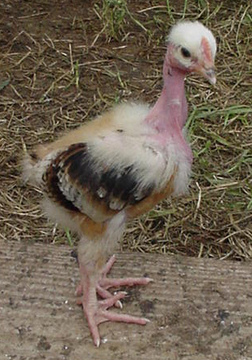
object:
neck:
[157, 80, 191, 117]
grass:
[0, 0, 252, 263]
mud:
[23, 7, 69, 32]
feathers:
[45, 136, 173, 220]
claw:
[76, 253, 155, 309]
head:
[169, 18, 219, 85]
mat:
[167, 273, 209, 324]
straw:
[225, 37, 246, 175]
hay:
[199, 99, 251, 179]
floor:
[151, 257, 238, 352]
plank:
[0, 232, 251, 360]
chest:
[144, 151, 193, 217]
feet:
[75, 287, 148, 345]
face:
[168, 19, 218, 88]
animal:
[20, 21, 216, 345]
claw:
[74, 279, 148, 347]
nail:
[94, 336, 100, 348]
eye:
[178, 44, 192, 67]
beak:
[200, 69, 219, 87]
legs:
[79, 226, 106, 306]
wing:
[43, 142, 166, 213]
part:
[161, 158, 177, 181]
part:
[209, 307, 227, 330]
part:
[50, 306, 64, 344]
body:
[17, 20, 216, 348]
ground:
[0, 0, 252, 360]